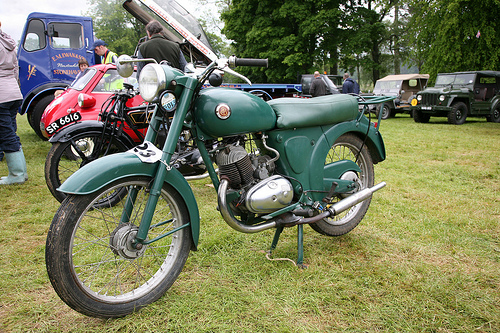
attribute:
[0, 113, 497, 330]
grass — green, brown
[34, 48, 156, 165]
vehicle — small, red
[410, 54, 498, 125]
cab — blue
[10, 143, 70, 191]
boots — light green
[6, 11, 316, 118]
truck — blue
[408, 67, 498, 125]
jeep — green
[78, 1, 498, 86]
trees — green 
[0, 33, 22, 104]
coat — pink 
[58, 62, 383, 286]
motorcycle — green, parked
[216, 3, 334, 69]
tree — large, green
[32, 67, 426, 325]
motorcycle — green, old school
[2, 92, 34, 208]
jeans — blue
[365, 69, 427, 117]
jeep — parked , brown 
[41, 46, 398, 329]
bike — green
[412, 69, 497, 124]
truck — black, parked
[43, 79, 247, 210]
motorcycle — black, parked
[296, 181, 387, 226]
pipe — chrome